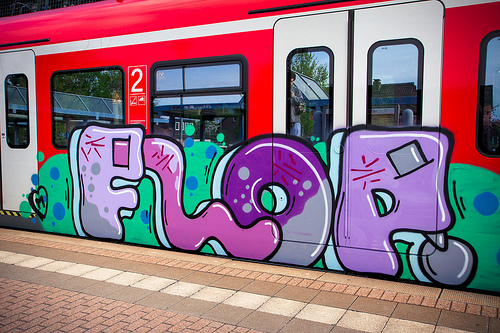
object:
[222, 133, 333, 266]
lettering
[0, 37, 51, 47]
lines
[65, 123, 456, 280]
word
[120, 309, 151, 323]
bricks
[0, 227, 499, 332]
sidewalk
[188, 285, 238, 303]
blocks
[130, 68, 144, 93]
2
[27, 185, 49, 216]
heart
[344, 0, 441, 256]
door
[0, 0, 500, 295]
train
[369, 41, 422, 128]
window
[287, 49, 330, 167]
window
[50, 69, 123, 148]
window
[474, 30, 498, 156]
window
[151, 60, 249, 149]
window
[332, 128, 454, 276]
graffiti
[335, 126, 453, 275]
lettering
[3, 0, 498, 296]
train car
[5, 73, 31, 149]
window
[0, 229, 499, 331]
platform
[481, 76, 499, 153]
reflection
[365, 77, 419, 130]
reflection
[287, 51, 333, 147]
reflection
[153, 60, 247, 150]
reflection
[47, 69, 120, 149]
reflection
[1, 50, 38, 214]
white doors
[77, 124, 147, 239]
letter f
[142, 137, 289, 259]
letter l